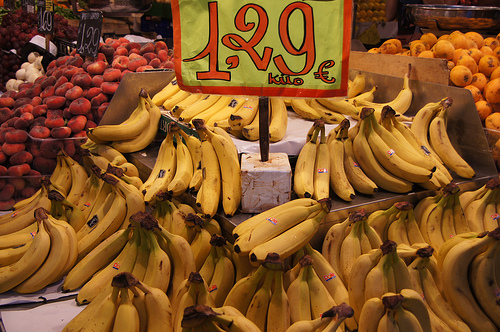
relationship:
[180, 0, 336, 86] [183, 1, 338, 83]
'1,29 kilo €' has price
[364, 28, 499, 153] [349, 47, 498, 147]
oranges in bin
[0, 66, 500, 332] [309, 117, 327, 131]
bananas have stem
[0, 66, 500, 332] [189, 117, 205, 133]
bananas have stem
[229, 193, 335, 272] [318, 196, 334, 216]
bananas have stem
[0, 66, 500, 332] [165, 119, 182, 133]
bananas have stem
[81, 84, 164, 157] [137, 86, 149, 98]
bananas have stem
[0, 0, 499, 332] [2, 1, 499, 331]
fruit in market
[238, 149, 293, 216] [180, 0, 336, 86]
block holds '1,29 kilo €'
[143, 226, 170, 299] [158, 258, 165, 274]
banana has spot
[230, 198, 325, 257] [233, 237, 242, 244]
banana has spot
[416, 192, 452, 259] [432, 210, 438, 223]
banana has spot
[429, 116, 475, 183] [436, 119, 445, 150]
banana has spot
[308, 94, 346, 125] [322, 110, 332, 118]
banana has spot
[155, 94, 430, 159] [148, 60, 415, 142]
paper beneath bananas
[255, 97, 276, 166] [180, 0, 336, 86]
pole holds '1,29 kilo €'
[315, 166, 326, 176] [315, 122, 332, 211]
sticker on banana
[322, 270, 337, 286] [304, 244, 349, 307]
sticker on banana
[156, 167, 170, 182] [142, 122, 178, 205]
sticker on banana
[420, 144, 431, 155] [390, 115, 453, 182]
sticker on banana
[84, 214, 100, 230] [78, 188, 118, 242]
sticker on banana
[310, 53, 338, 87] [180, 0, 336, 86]
euro symbol on '1,29 kilo €'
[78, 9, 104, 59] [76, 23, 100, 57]
sign has price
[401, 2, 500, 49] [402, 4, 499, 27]
scale has bowl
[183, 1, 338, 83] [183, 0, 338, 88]
price has black outline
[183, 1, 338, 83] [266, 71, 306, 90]
price in kilos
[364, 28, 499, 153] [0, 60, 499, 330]
oranges to right of bananas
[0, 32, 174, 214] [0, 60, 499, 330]
peaches to left of bananas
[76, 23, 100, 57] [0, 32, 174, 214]
price for peaches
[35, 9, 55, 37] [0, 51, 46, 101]
sign for coconuts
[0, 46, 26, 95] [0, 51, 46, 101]
plums behind coconuts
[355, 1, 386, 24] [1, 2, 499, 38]
lemons in back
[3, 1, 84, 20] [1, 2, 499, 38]
vegetables in back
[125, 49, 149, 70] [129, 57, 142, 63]
peach has bruise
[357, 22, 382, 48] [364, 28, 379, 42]
sign has price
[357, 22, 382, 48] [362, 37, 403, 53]
sign on floor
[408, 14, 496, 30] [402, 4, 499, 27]
reflection in bowl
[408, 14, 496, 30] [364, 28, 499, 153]
reflection of oranges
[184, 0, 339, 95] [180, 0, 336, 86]
'1,29 kilo €' on '1,29 kilo €'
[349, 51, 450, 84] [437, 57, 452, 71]
thin wood has chewed corner